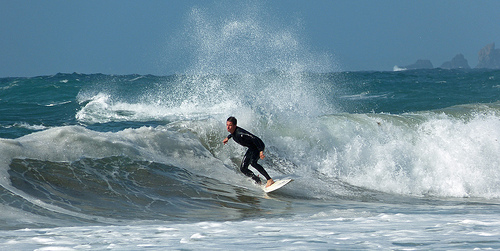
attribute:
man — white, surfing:
[205, 114, 292, 197]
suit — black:
[232, 135, 274, 173]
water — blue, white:
[23, 75, 442, 217]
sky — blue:
[17, 2, 439, 83]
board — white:
[266, 175, 289, 195]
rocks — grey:
[387, 47, 499, 82]